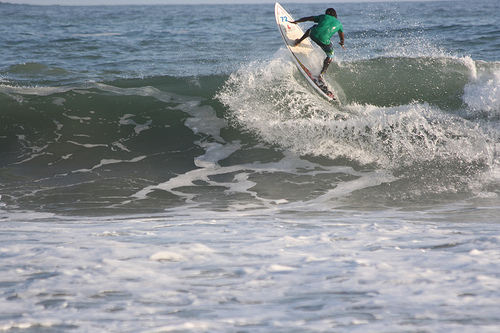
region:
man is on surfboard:
[261, 3, 361, 78]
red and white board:
[268, 21, 330, 96]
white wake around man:
[276, 60, 368, 112]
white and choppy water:
[197, 182, 369, 328]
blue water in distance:
[79, 3, 181, 88]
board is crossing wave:
[267, 15, 336, 97]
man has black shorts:
[282, 15, 355, 81]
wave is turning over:
[54, 78, 169, 124]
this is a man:
[297, 1, 355, 56]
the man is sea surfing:
[289, 5, 349, 58]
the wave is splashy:
[239, 53, 285, 98]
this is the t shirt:
[316, 13, 333, 36]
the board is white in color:
[284, 25, 299, 37]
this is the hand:
[337, 30, 351, 47]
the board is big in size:
[274, 0, 299, 34]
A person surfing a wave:
[258, 0, 359, 127]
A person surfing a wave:
[263, 0, 350, 116]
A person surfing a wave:
[265, 0, 355, 122]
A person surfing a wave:
[265, 1, 360, 114]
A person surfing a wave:
[267, 0, 348, 118]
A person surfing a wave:
[263, 1, 356, 112]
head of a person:
[325, 1, 342, 26]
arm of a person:
[286, 11, 311, 33]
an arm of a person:
[293, 4, 313, 21]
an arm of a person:
[328, 25, 359, 51]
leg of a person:
[292, 17, 320, 41]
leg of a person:
[312, 44, 346, 84]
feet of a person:
[276, 34, 308, 56]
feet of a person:
[300, 71, 344, 89]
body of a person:
[303, 16, 350, 52]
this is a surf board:
[267, 1, 334, 102]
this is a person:
[307, 1, 351, 69]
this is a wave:
[0, 39, 467, 158]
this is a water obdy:
[8, 5, 493, 323]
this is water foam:
[177, 94, 231, 186]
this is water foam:
[209, 156, 363, 186]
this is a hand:
[336, 27, 351, 56]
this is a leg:
[319, 44, 336, 88]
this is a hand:
[287, 12, 315, 26]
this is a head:
[325, 0, 339, 22]